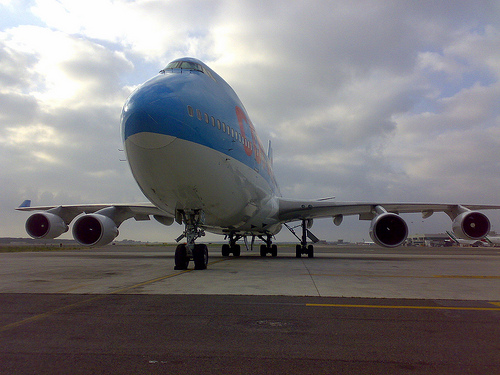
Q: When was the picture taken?
A: Cloudy day.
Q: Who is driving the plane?
A: Pilot.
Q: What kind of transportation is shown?
A: Airplane.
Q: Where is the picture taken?
A: Runway.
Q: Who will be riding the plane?
A: Passengers.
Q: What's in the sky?
A: Clouds.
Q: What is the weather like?
A: Cloudy.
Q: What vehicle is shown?
A: Airplane.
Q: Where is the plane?
A: On runway.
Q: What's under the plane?
A: Wheels.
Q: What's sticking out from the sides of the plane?
A: Wings.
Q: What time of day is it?
A: Morning.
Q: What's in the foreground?
A: Road.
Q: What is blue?
A: Plane.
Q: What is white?
A: Clouds.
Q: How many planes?
A: One.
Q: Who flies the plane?
A: Man.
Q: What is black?
A: Wheels.